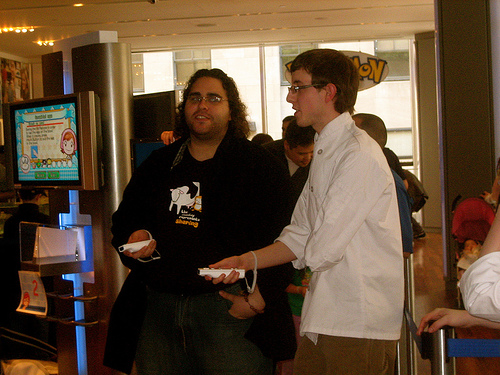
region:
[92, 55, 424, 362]
these two guys are playing a game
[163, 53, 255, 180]
this man has longish hair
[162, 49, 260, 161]
this hair is very dark & appears very curly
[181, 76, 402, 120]
both men are wearing glasses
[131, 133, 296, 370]
this man is dressed in black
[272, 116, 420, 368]
this fella has on a white shirt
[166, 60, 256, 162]
this man has facial hair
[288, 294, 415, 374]
this man has on brown pants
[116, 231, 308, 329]
the game controllers are white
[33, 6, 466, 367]
these people are in a public place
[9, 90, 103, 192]
television with the screen on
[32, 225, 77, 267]
white wii game system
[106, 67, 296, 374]
man in black holding wii controller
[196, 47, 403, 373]
man in white shirt holding wii controller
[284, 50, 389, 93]
sign in the back with the Pokemon logo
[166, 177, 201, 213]
cow graphic on the man's shirt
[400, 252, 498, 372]
silver poles and blue tape that make a barrier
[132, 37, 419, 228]
glass windows in the background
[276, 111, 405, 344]
white chef jacket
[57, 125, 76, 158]
face on the television screen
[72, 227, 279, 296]
Wii remotes in the men's hands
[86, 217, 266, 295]
The Wii remotes are white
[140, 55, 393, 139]
Two men with glasses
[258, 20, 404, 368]
Man wearing a white shirt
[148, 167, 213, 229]
Cow on the man's shirt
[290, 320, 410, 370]
Brown pants on the man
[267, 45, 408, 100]
Pokemon sign behind the men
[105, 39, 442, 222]
Sunlight coming through the window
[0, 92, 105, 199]
A monitor turned on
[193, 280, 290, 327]
The man's left hand is in his pocket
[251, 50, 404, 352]
man playing wii in white shirt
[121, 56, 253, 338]
man playing wii in dark colors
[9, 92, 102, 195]
flat monitor with video game displayed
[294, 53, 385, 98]
pokemon display in background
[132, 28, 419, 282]
sliding glass door in background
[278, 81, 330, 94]
eye glasses on MAN IN WHITE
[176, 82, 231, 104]
EYEGLASSES ON MAN IN BLACK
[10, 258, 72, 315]
PIECE OF PAPER HANGING WITH 2 ON IT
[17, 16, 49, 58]
SMALL ROWS OF LIGHTS ON CEILING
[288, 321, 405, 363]
LIGHT BROWN CORDUROY PANTS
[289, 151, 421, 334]
white chef dress shirt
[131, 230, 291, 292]
a set of two wii remotes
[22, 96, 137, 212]
a flat screen TV on wall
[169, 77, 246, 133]
a man with long brown hair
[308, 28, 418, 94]
a partial sticker of Pokemon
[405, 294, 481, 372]
a blue and silver pole with rope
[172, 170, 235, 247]
a cow on the man's shirt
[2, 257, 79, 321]
a paper flyer on shelf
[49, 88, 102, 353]
a blue bright light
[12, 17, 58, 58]
recess row lighting on ceiling